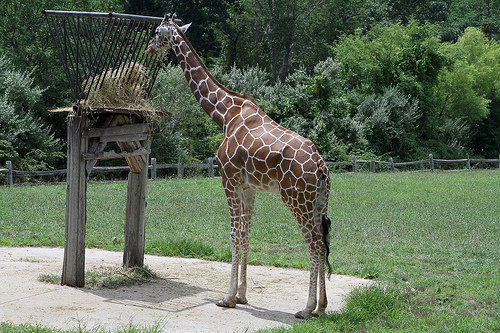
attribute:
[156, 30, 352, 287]
giraffe — eating, standing, tall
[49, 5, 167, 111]
feeding bin — black, wooden, tall, metal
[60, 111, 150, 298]
stand — small, wooden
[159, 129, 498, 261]
meadow — grassy, green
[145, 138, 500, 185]
fence — wooden, low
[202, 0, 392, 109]
trees — green, tall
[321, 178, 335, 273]
tail — black, curly, long, fuzzy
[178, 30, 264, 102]
mane — short, brown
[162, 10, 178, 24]
horns — black, short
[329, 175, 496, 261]
grass — brown, green, short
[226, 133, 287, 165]
spots — brown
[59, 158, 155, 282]
poles — wooden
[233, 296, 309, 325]
shadow — small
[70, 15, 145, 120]
container — metal